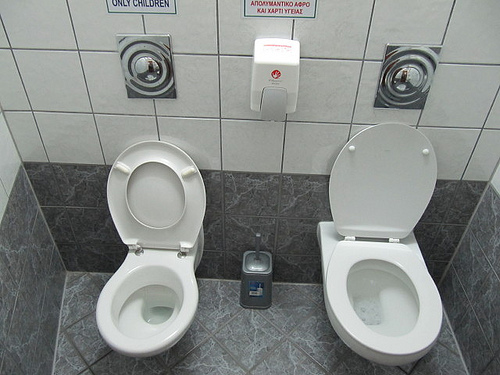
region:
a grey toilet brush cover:
[239, 228, 271, 321]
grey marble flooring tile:
[229, 318, 279, 374]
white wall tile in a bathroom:
[189, 53, 229, 116]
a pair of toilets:
[53, 57, 442, 374]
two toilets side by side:
[64, 73, 466, 373]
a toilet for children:
[86, 116, 203, 370]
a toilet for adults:
[308, 85, 451, 374]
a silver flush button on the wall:
[357, 21, 454, 116]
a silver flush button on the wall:
[112, 21, 181, 111]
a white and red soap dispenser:
[242, 28, 308, 138]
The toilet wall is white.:
[22, 26, 104, 161]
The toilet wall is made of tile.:
[17, 43, 104, 160]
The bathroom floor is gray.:
[214, 325, 309, 370]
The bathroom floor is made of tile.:
[213, 321, 321, 373]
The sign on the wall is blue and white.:
[102, 0, 182, 19]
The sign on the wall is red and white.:
[242, 0, 320, 18]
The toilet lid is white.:
[97, 136, 211, 251]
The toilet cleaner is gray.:
[231, 226, 283, 311]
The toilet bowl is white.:
[93, 247, 200, 359]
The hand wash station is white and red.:
[246, 38, 306, 126]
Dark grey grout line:
[29, 105, 101, 130]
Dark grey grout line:
[91, 101, 153, 124]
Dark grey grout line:
[159, 106, 214, 130]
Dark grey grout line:
[219, 108, 276, 138]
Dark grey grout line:
[297, 113, 338, 146]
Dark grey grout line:
[343, 42, 371, 117]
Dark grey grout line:
[182, 41, 234, 70]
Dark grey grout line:
[13, 37, 60, 57]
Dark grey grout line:
[360, 12, 430, 27]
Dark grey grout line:
[459, 111, 499, 138]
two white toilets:
[79, 117, 446, 372]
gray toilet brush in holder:
[234, 232, 278, 314]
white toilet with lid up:
[306, 117, 463, 358]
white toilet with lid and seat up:
[93, 142, 219, 355]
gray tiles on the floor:
[61, 272, 456, 372]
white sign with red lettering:
[245, 1, 319, 18]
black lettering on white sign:
[107, 2, 174, 11]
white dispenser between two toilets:
[247, 36, 303, 118]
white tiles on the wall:
[2, 5, 499, 167]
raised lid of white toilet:
[324, 122, 439, 240]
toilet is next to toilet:
[93, 141, 203, 358]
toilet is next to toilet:
[316, 124, 444, 365]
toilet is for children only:
[95, 141, 204, 357]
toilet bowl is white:
[93, 252, 200, 357]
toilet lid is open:
[327, 123, 439, 239]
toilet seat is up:
[105, 142, 205, 252]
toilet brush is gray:
[239, 234, 273, 309]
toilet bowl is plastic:
[242, 232, 273, 310]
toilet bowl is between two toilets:
[242, 232, 277, 310]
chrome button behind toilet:
[116, 34, 175, 99]